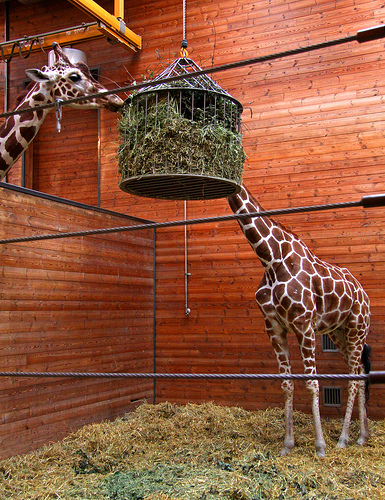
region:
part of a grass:
[190, 413, 210, 426]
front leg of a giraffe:
[313, 397, 323, 420]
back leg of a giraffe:
[345, 403, 352, 424]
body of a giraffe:
[315, 275, 324, 288]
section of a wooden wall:
[67, 292, 95, 317]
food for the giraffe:
[206, 427, 258, 452]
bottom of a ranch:
[99, 404, 108, 412]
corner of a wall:
[153, 301, 160, 320]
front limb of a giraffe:
[291, 295, 308, 316]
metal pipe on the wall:
[162, 184, 214, 332]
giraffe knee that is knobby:
[300, 363, 332, 404]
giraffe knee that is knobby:
[271, 373, 299, 402]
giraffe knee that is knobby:
[339, 368, 363, 399]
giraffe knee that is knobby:
[347, 367, 370, 403]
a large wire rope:
[0, 356, 384, 395]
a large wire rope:
[0, 188, 382, 272]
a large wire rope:
[0, 15, 382, 122]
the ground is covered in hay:
[1, 377, 384, 499]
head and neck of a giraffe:
[0, 30, 129, 193]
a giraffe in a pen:
[183, 132, 381, 463]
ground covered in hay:
[4, 384, 383, 494]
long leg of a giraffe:
[292, 312, 328, 461]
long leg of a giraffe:
[271, 315, 305, 464]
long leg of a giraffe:
[327, 314, 376, 451]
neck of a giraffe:
[195, 168, 303, 274]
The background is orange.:
[109, 435, 205, 476]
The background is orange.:
[111, 440, 259, 493]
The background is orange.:
[154, 438, 193, 493]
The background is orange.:
[147, 368, 175, 401]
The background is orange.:
[125, 347, 247, 382]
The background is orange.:
[135, 352, 248, 364]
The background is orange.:
[117, 330, 179, 344]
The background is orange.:
[123, 339, 170, 376]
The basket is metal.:
[118, 53, 243, 201]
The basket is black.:
[116, 53, 241, 204]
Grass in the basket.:
[116, 51, 245, 198]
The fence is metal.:
[0, 187, 383, 393]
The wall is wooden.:
[1, 0, 383, 447]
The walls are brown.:
[1, 2, 383, 461]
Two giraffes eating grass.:
[22, 37, 269, 223]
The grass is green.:
[115, 94, 244, 183]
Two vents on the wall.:
[312, 322, 353, 412]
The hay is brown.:
[2, 385, 382, 498]